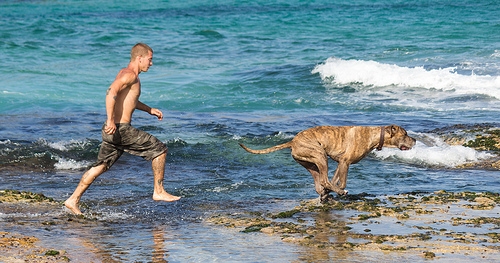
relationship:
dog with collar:
[245, 115, 416, 192] [378, 125, 389, 154]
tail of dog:
[240, 138, 294, 156] [245, 115, 416, 192]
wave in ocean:
[313, 60, 497, 108] [0, 3, 497, 211]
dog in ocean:
[245, 115, 416, 192] [0, 3, 497, 211]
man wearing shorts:
[61, 41, 173, 214] [90, 125, 164, 164]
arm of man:
[104, 70, 136, 134] [61, 41, 173, 214]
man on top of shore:
[61, 41, 173, 214] [4, 176, 496, 262]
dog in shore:
[245, 115, 416, 192] [4, 176, 496, 262]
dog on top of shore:
[245, 115, 416, 192] [4, 176, 496, 262]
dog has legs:
[245, 115, 416, 192] [300, 154, 353, 196]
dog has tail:
[245, 115, 416, 192] [240, 138, 294, 156]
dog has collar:
[245, 115, 416, 192] [378, 125, 389, 154]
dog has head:
[245, 115, 416, 192] [385, 124, 416, 150]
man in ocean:
[61, 41, 173, 214] [0, 3, 497, 211]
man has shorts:
[61, 41, 173, 214] [90, 125, 164, 164]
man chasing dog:
[61, 41, 173, 214] [245, 115, 416, 192]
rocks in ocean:
[7, 137, 103, 168] [0, 3, 497, 211]